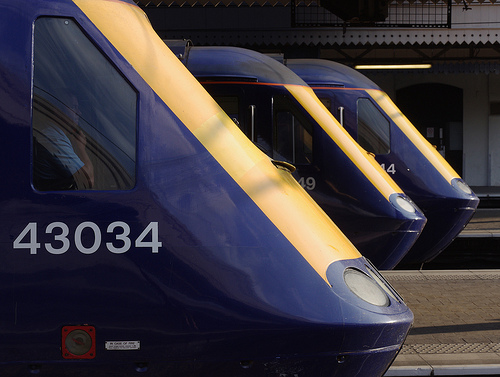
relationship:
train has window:
[1, 1, 413, 376] [30, 16, 135, 194]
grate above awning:
[292, 4, 487, 44] [313, 50, 490, 70]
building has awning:
[141, 0, 499, 193] [313, 50, 490, 70]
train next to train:
[1, 1, 413, 376] [158, 37, 428, 267]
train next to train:
[158, 37, 428, 267] [264, 51, 480, 269]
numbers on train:
[12, 218, 166, 255] [1, 1, 413, 376]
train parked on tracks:
[0, 1, 412, 376] [356, 190, 498, 375]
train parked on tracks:
[158, 37, 428, 271] [356, 190, 498, 375]